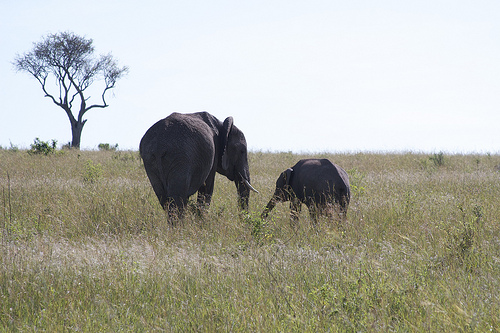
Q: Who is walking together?
A: Two elephants.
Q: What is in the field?
A: A single tree.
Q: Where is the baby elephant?
A: In the grass.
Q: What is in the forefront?
A: A patch of lighter grass.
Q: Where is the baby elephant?
A: In the tall grass.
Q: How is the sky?
A: It is cloudy.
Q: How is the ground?
A: It has tall dried grass.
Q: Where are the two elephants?
A: In the grass.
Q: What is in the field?
A: A lot of grass.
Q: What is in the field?
A: Two elephants.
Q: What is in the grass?
A: The elephants.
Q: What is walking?
A: The elephants.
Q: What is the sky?
A: Clear blue.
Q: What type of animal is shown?
A: Elephant.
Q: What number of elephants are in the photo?
A: 2.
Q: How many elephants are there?
A: Two.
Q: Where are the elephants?
A: In the field.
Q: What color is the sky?
A: Blue.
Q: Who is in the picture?
A: Two elephants.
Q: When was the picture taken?
A: The daytime.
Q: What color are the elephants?
A: Brown.